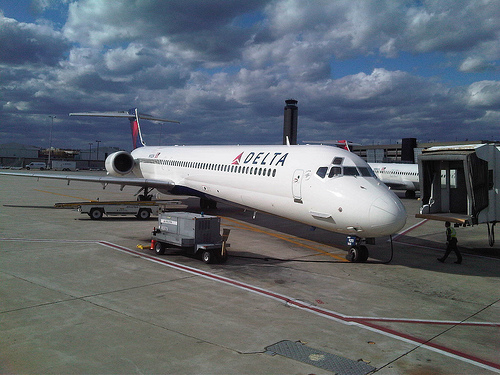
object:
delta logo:
[241, 151, 288, 167]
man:
[437, 220, 462, 265]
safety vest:
[446, 225, 458, 241]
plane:
[0, 105, 408, 263]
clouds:
[0, 8, 73, 69]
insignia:
[231, 150, 245, 165]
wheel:
[347, 244, 363, 263]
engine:
[104, 150, 135, 178]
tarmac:
[0, 164, 500, 375]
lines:
[342, 313, 500, 327]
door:
[291, 168, 305, 200]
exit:
[291, 169, 304, 200]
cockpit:
[315, 155, 376, 181]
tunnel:
[417, 141, 500, 230]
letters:
[242, 151, 256, 163]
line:
[94, 239, 499, 375]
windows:
[315, 167, 327, 179]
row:
[139, 158, 278, 178]